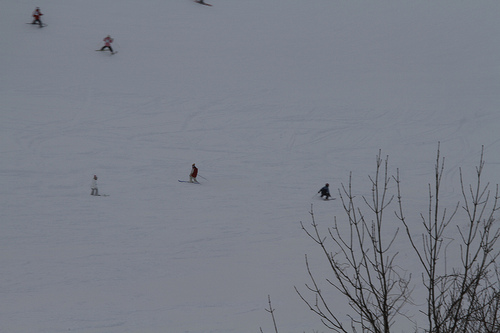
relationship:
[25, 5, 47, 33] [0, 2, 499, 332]
person skiing down hill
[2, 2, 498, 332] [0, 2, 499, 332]
snow on surface of hill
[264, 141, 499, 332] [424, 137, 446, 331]
tree has branch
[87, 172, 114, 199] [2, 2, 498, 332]
skater on top of snow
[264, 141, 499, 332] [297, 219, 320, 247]
tree has twig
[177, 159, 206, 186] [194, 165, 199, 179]
man has back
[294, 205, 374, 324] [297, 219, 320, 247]
branch has twig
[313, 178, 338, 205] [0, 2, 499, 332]
skier skiing down hill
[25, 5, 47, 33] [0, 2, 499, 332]
person skiing on hill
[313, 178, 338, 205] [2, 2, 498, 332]
skier carving in snow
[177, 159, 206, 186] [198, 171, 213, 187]
man has pole